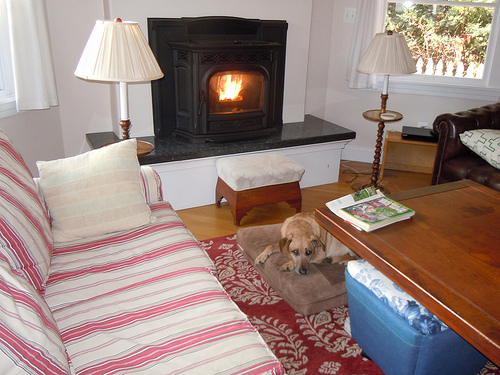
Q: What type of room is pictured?
A: It is a living room.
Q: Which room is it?
A: It is a living room.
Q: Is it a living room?
A: Yes, it is a living room.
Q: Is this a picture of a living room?
A: Yes, it is showing a living room.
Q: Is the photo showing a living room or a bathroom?
A: It is showing a living room.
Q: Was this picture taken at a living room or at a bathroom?
A: It was taken at a living room.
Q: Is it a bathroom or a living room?
A: It is a living room.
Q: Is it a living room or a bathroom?
A: It is a living room.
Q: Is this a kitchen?
A: No, it is a living room.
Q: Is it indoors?
A: Yes, it is indoors.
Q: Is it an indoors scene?
A: Yes, it is indoors.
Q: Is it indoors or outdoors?
A: It is indoors.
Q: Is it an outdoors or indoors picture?
A: It is indoors.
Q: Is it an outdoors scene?
A: No, it is indoors.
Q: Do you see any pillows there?
A: Yes, there is a pillow.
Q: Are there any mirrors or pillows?
A: Yes, there is a pillow.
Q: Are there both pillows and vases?
A: No, there is a pillow but no vases.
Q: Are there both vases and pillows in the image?
A: No, there is a pillow but no vases.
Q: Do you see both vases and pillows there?
A: No, there is a pillow but no vases.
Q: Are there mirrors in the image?
A: No, there are no mirrors.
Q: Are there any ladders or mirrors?
A: No, there are no mirrors or ladders.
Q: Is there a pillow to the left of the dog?
A: Yes, there is a pillow to the left of the dog.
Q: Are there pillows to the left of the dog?
A: Yes, there is a pillow to the left of the dog.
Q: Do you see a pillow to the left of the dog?
A: Yes, there is a pillow to the left of the dog.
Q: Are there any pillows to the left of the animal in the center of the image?
A: Yes, there is a pillow to the left of the dog.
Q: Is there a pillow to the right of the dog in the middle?
A: No, the pillow is to the left of the dog.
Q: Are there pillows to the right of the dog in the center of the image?
A: No, the pillow is to the left of the dog.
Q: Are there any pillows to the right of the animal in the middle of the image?
A: No, the pillow is to the left of the dog.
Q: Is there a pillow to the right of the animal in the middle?
A: No, the pillow is to the left of the dog.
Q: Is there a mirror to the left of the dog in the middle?
A: No, there is a pillow to the left of the dog.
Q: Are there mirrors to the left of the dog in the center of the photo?
A: No, there is a pillow to the left of the dog.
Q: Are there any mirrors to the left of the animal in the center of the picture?
A: No, there is a pillow to the left of the dog.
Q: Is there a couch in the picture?
A: Yes, there is a couch.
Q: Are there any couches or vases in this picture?
A: Yes, there is a couch.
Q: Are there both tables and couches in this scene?
A: Yes, there are both a couch and a table.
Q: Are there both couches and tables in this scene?
A: Yes, there are both a couch and a table.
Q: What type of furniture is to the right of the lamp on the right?
A: The piece of furniture is a couch.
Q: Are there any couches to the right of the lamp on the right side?
A: Yes, there is a couch to the right of the lamp.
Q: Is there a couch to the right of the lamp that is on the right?
A: Yes, there is a couch to the right of the lamp.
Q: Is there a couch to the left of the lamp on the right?
A: No, the couch is to the right of the lamp.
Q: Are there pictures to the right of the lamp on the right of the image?
A: No, there is a couch to the right of the lamp.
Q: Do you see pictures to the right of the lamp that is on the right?
A: No, there is a couch to the right of the lamp.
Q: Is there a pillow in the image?
A: Yes, there is a pillow.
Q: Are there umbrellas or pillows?
A: Yes, there is a pillow.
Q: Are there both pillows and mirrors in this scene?
A: No, there is a pillow but no mirrors.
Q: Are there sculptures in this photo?
A: No, there are no sculptures.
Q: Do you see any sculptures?
A: No, there are no sculptures.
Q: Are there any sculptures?
A: No, there are no sculptures.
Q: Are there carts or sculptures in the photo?
A: No, there are no sculptures or carts.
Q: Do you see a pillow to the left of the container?
A: Yes, there is a pillow to the left of the container.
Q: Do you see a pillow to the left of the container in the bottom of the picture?
A: Yes, there is a pillow to the left of the container.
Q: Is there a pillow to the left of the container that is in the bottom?
A: Yes, there is a pillow to the left of the container.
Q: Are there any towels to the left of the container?
A: No, there is a pillow to the left of the container.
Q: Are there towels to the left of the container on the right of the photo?
A: No, there is a pillow to the left of the container.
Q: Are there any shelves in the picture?
A: No, there are no shelves.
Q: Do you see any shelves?
A: No, there are no shelves.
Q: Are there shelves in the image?
A: No, there are no shelves.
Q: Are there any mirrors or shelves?
A: No, there are no shelves or mirrors.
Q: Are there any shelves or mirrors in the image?
A: No, there are no shelves or mirrors.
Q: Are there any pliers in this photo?
A: No, there are no pliers.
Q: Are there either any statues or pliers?
A: No, there are no pliers or statues.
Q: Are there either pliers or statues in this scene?
A: No, there are no pliers or statues.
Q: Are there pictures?
A: No, there are no pictures.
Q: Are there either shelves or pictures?
A: No, there are no pictures or shelves.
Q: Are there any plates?
A: No, there are no plates.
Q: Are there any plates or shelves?
A: No, there are no plates or shelves.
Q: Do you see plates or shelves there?
A: No, there are no plates or shelves.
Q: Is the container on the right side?
A: Yes, the container is on the right of the image.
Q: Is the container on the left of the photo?
A: No, the container is on the right of the image.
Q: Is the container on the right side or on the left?
A: The container is on the right of the image.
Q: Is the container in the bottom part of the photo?
A: Yes, the container is in the bottom of the image.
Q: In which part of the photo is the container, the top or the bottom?
A: The container is in the bottom of the image.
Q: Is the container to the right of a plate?
A: No, the container is to the right of a couch.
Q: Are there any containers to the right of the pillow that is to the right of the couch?
A: Yes, there is a container to the right of the pillow.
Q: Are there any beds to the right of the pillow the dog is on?
A: No, there is a container to the right of the pillow.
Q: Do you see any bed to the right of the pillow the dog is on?
A: No, there is a container to the right of the pillow.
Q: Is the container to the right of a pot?
A: No, the container is to the right of the pillow.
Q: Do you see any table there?
A: Yes, there is a table.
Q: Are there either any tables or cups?
A: Yes, there is a table.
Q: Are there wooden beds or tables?
A: Yes, there is a wood table.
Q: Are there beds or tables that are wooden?
A: Yes, the table is wooden.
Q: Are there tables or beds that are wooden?
A: Yes, the table is wooden.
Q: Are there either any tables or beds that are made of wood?
A: Yes, the table is made of wood.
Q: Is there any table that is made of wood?
A: Yes, there is a table that is made of wood.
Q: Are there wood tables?
A: Yes, there is a table that is made of wood.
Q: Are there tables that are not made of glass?
A: Yes, there is a table that is made of wood.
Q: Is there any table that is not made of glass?
A: Yes, there is a table that is made of wood.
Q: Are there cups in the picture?
A: No, there are no cups.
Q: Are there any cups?
A: No, there are no cups.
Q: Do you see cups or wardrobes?
A: No, there are no cups or wardrobes.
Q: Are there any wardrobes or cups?
A: No, there are no cups or wardrobes.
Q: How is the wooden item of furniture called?
A: The piece of furniture is a table.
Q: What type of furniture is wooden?
A: The furniture is a table.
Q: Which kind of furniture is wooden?
A: The furniture is a table.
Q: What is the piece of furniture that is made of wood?
A: The piece of furniture is a table.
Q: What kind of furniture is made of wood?
A: The furniture is a table.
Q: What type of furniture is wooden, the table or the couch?
A: The table is wooden.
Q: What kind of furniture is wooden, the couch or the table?
A: The table is wooden.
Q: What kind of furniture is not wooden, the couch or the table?
A: The couch is not wooden.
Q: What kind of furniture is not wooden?
A: The furniture is a couch.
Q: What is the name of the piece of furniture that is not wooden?
A: The piece of furniture is a couch.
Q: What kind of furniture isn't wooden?
A: The furniture is a couch.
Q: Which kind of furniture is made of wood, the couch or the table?
A: The table is made of wood.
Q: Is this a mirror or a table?
A: This is a table.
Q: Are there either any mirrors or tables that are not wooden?
A: No, there is a table but it is wooden.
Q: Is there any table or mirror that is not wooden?
A: No, there is a table but it is wooden.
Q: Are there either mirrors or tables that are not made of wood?
A: No, there is a table but it is made of wood.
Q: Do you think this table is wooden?
A: Yes, the table is wooden.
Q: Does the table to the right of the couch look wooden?
A: Yes, the table is wooden.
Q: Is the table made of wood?
A: Yes, the table is made of wood.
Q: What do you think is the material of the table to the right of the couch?
A: The table is made of wood.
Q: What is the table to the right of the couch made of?
A: The table is made of wood.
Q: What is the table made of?
A: The table is made of wood.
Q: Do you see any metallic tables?
A: No, there is a table but it is wooden.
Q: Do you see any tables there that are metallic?
A: No, there is a table but it is wooden.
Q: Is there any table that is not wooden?
A: No, there is a table but it is wooden.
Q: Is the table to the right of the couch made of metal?
A: No, the table is made of wood.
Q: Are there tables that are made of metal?
A: No, there is a table but it is made of wood.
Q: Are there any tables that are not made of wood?
A: No, there is a table but it is made of wood.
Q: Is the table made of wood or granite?
A: The table is made of wood.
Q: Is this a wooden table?
A: Yes, this is a wooden table.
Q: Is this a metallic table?
A: No, this is a wooden table.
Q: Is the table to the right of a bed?
A: No, the table is to the right of the couch.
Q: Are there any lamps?
A: Yes, there is a lamp.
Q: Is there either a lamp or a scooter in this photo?
A: Yes, there is a lamp.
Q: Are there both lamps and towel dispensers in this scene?
A: No, there is a lamp but no towel dispensers.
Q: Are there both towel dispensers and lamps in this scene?
A: No, there is a lamp but no towel dispensers.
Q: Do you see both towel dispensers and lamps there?
A: No, there is a lamp but no towel dispensers.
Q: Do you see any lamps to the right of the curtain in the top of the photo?
A: Yes, there is a lamp to the right of the curtain.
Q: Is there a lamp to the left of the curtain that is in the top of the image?
A: No, the lamp is to the right of the curtain.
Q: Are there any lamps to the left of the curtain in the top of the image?
A: No, the lamp is to the right of the curtain.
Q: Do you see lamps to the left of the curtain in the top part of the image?
A: No, the lamp is to the right of the curtain.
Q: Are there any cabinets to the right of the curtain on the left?
A: No, there is a lamp to the right of the curtain.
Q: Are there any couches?
A: Yes, there is a couch.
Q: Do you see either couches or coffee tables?
A: Yes, there is a couch.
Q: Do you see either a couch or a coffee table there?
A: Yes, there is a couch.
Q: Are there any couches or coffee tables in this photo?
A: Yes, there is a couch.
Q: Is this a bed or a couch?
A: This is a couch.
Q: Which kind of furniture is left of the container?
A: The piece of furniture is a couch.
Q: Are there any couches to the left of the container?
A: Yes, there is a couch to the left of the container.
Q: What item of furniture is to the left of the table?
A: The piece of furniture is a couch.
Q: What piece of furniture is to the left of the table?
A: The piece of furniture is a couch.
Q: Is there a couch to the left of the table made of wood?
A: Yes, there is a couch to the left of the table.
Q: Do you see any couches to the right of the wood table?
A: No, the couch is to the left of the table.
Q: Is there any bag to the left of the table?
A: No, there is a couch to the left of the table.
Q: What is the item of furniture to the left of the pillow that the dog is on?
A: The piece of furniture is a couch.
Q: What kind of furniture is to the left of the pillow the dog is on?
A: The piece of furniture is a couch.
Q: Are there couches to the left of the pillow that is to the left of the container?
A: Yes, there is a couch to the left of the pillow.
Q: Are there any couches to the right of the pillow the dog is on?
A: No, the couch is to the left of the pillow.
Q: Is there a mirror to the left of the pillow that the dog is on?
A: No, there is a couch to the left of the pillow.